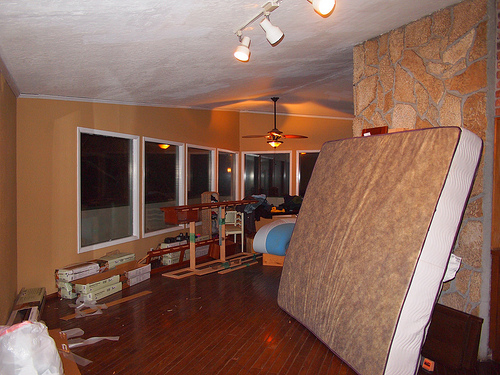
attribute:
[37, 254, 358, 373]
floor — wood, brown, natural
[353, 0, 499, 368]
wall — stone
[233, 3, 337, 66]
lights — white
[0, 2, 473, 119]
ceiling — white, stucco, textured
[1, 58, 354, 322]
wall — ornage, tan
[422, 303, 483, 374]
bed frame — wood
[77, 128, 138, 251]
trim — white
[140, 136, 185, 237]
trim — white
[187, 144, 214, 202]
trim — white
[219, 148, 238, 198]
trim — white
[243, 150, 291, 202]
trim — white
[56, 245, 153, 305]
flooring package — natural, wood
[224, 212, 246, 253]
chair — white